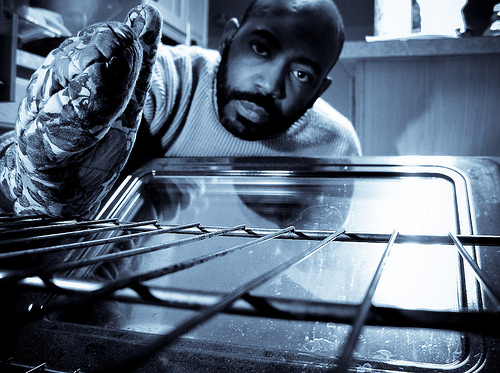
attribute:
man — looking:
[139, 0, 358, 156]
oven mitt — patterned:
[0, 2, 162, 219]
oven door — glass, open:
[38, 156, 498, 370]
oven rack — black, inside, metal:
[0, 212, 499, 373]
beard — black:
[220, 60, 313, 139]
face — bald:
[218, 0, 348, 146]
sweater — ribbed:
[145, 46, 358, 156]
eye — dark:
[248, 41, 276, 60]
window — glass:
[63, 150, 490, 371]